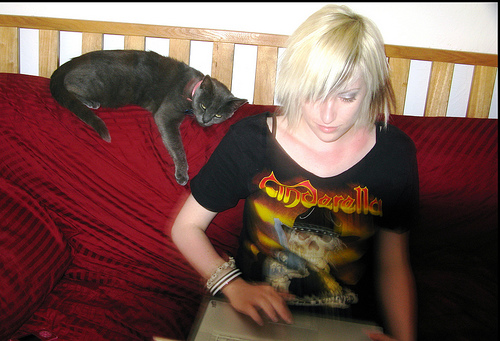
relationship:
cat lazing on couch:
[48, 47, 247, 186] [0, 72, 499, 339]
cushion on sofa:
[0, 70, 494, 339] [4, 13, 499, 337]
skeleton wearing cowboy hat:
[288, 230, 341, 267] [279, 203, 361, 236]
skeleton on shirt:
[288, 230, 341, 267] [183, 123, 420, 320]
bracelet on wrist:
[208, 270, 240, 294] [190, 237, 282, 317]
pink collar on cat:
[190, 72, 205, 97] [49, 50, 246, 145]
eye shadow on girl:
[333, 85, 361, 100] [173, 17, 419, 339]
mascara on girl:
[338, 93, 364, 102] [173, 17, 419, 339]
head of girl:
[274, 5, 381, 142] [170, 5, 424, 341]